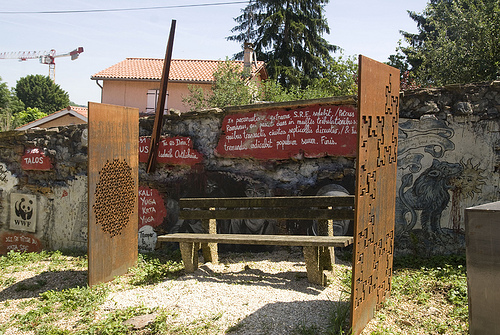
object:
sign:
[1, 193, 44, 259]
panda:
[13, 198, 37, 220]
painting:
[395, 157, 462, 241]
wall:
[392, 95, 500, 256]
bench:
[157, 196, 356, 286]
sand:
[191, 279, 249, 311]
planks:
[350, 54, 401, 333]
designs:
[360, 72, 401, 175]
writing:
[223, 108, 357, 150]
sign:
[20, 152, 51, 170]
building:
[90, 58, 268, 112]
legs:
[178, 240, 221, 274]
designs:
[94, 156, 138, 236]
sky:
[0, 1, 428, 108]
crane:
[0, 42, 82, 83]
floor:
[1, 249, 469, 334]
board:
[86, 102, 140, 288]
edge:
[78, 138, 98, 166]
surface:
[107, 125, 119, 136]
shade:
[0, 268, 89, 301]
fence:
[0, 119, 89, 136]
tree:
[226, 1, 340, 94]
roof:
[90, 56, 272, 84]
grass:
[400, 260, 461, 291]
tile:
[143, 60, 155, 70]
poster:
[7, 193, 40, 235]